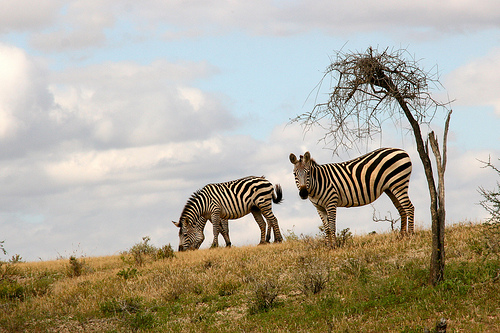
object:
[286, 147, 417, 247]
zebra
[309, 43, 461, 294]
tree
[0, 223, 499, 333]
grass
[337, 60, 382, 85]
branches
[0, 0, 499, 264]
clouds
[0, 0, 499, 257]
sky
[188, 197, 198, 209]
fur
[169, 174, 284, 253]
zebra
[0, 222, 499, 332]
hill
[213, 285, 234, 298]
shrub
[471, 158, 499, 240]
bush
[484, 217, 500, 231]
branches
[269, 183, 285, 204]
tail